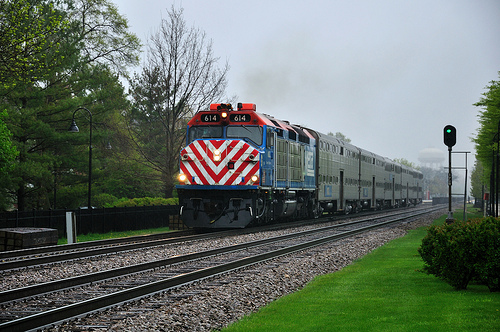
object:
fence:
[4, 201, 176, 236]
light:
[221, 112, 228, 119]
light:
[178, 172, 188, 182]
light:
[251, 174, 259, 182]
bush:
[414, 212, 499, 293]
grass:
[373, 261, 402, 288]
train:
[172, 102, 424, 228]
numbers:
[204, 115, 209, 122]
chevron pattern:
[179, 139, 260, 186]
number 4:
[212, 114, 217, 122]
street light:
[68, 104, 93, 209]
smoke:
[247, 52, 355, 114]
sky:
[93, 2, 499, 196]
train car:
[317, 130, 361, 210]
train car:
[358, 145, 394, 208]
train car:
[403, 167, 426, 200]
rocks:
[0, 203, 470, 329]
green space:
[221, 201, 499, 330]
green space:
[45, 218, 171, 245]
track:
[0, 196, 453, 330]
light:
[446, 128, 453, 134]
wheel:
[310, 204, 324, 219]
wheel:
[345, 203, 353, 215]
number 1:
[209, 115, 212, 122]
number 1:
[238, 115, 241, 122]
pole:
[440, 121, 459, 221]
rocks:
[126, 276, 246, 328]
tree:
[119, 0, 240, 198]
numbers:
[242, 114, 246, 121]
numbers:
[204, 114, 217, 121]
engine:
[169, 101, 325, 232]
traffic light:
[443, 127, 458, 147]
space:
[245, 222, 495, 324]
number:
[234, 115, 246, 122]